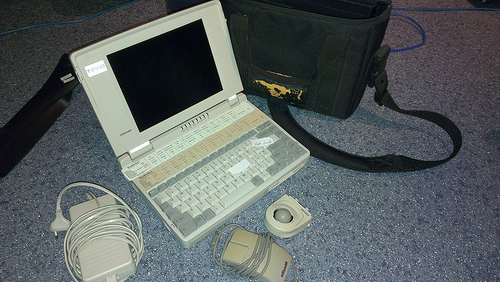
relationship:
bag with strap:
[226, 2, 392, 119] [269, 104, 429, 176]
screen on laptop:
[99, 18, 220, 134] [59, 0, 331, 246]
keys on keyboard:
[168, 186, 196, 210] [148, 125, 303, 245]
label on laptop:
[79, 62, 110, 82] [59, 0, 331, 246]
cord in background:
[17, 3, 135, 36] [2, 0, 500, 63]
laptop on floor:
[59, 0, 331, 246] [8, 69, 492, 281]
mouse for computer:
[215, 232, 289, 282] [59, 0, 331, 246]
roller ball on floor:
[266, 192, 311, 239] [8, 69, 492, 281]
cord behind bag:
[17, 3, 135, 36] [226, 2, 392, 119]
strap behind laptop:
[5, 74, 67, 174] [59, 0, 331, 246]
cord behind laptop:
[17, 3, 135, 36] [59, 0, 331, 246]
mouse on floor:
[215, 232, 289, 282] [8, 69, 492, 281]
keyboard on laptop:
[148, 125, 303, 245] [59, 0, 331, 246]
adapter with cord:
[66, 206, 136, 281] [79, 215, 111, 231]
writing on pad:
[279, 260, 291, 277] [261, 243, 288, 282]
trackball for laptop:
[266, 192, 311, 239] [59, 0, 331, 246]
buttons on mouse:
[220, 231, 260, 262] [215, 232, 289, 282]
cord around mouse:
[79, 215, 111, 231] [215, 232, 289, 282]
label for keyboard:
[79, 62, 110, 82] [148, 125, 303, 245]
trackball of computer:
[266, 192, 311, 239] [59, 0, 331, 246]